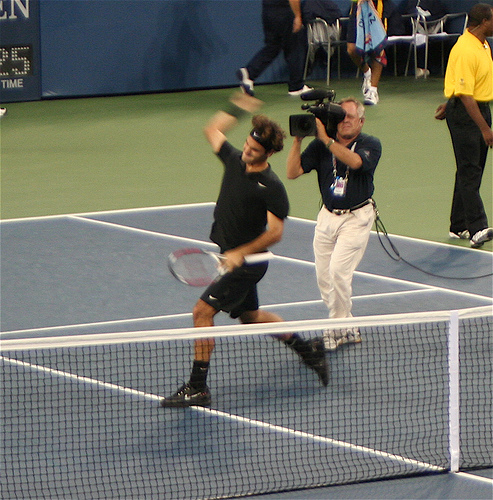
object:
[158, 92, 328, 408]
man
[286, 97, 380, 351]
man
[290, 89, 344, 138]
video camera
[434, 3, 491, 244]
man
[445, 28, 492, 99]
shirt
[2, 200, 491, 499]
tennis court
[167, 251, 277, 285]
racket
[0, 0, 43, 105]
display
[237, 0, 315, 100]
person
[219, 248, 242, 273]
hand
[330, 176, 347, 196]
vip media pass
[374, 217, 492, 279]
cable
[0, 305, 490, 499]
net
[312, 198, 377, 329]
pants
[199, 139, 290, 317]
clothing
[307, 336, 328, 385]
shoe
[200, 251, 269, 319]
shorts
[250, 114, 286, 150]
hair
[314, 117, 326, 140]
hand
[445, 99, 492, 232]
pants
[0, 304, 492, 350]
top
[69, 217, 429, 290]
line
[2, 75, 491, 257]
part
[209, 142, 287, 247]
shirt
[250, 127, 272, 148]
headband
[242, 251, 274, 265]
handle